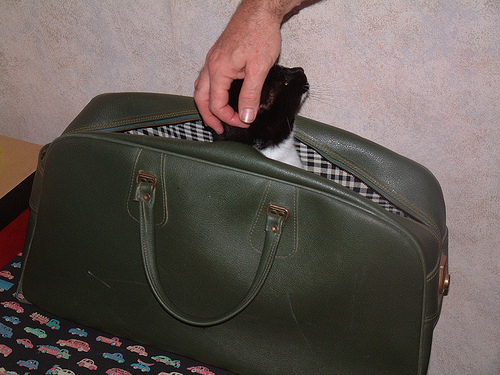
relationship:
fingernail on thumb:
[241, 107, 255, 123] [237, 63, 273, 124]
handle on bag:
[132, 182, 289, 325] [19, 93, 450, 374]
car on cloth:
[76, 358, 96, 371] [0, 248, 227, 374]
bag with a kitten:
[19, 93, 450, 374] [206, 65, 309, 172]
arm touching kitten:
[238, 0, 308, 21] [206, 65, 309, 172]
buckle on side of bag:
[435, 254, 451, 314] [19, 93, 450, 374]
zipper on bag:
[75, 122, 440, 235] [19, 93, 450, 374]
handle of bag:
[132, 182, 289, 325] [19, 93, 450, 374]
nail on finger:
[213, 126, 219, 134] [192, 74, 223, 136]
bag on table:
[19, 93, 450, 374] [0, 134, 46, 200]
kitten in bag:
[206, 65, 309, 172] [19, 93, 450, 374]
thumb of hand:
[237, 63, 273, 124] [195, 17, 282, 135]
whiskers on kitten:
[285, 83, 320, 129] [206, 65, 309, 172]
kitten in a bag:
[206, 65, 309, 172] [19, 93, 450, 374]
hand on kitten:
[195, 17, 282, 135] [206, 65, 309, 172]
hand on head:
[195, 17, 282, 135] [212, 67, 310, 136]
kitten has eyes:
[206, 65, 309, 172] [255, 84, 278, 114]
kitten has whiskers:
[206, 65, 309, 172] [285, 83, 320, 129]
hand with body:
[195, 17, 282, 135] [349, 0, 373, 1]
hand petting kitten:
[195, 17, 282, 135] [206, 65, 309, 172]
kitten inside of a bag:
[206, 65, 309, 172] [19, 93, 450, 374]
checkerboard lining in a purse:
[120, 119, 213, 142] [19, 93, 450, 374]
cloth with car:
[0, 248, 227, 374] [76, 358, 96, 371]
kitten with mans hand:
[206, 65, 309, 172] [195, 17, 282, 135]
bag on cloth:
[19, 93, 450, 374] [0, 248, 227, 374]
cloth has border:
[0, 248, 227, 374] [0, 206, 35, 271]